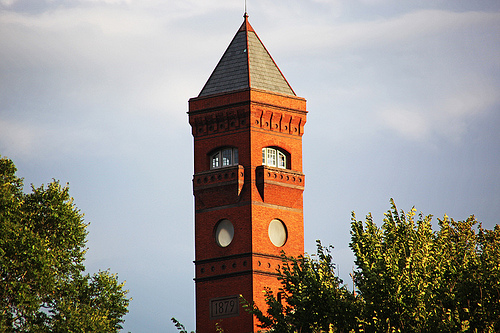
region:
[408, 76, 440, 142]
There is a bright white cloud that is in the distance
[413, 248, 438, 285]
There is a green tree that is visible here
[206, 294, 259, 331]
This tower says "1879" on it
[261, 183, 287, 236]
There is a deep red brick color that is evident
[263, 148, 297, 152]
There is a window in this tower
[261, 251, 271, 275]
There are circles that are emblazoned in the building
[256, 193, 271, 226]
There is a gray line that is visible here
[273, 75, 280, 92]
There is a gray roof that is very visible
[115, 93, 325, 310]
Jackson Mingus took this photo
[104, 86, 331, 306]
This photo has a great deal of detail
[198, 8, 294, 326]
red clock tower in center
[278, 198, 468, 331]
green tree below tower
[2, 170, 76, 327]
green tree below tower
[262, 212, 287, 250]
round glass window on tower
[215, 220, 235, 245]
round glass window on tower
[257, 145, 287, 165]
glass windows on tower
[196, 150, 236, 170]
glass windows on tower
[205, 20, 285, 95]
gray roof of tower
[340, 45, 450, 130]
white clouds in sky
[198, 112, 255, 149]
red brick wall of tower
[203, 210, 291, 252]
two round circles on face of tower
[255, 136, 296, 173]
long arched window on front of tower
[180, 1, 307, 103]
steeple at top of tower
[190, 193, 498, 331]
tall green tree tops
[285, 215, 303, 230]
red bricks on front of tower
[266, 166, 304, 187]
round circular design on front of tower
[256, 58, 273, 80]
grey tiles on top of tower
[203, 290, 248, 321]
year engraved on front of tower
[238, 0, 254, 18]
metal rod at very top of tower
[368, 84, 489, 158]
misty white cloud in grey sky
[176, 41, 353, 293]
a building with a window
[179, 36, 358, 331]
a tall building with a window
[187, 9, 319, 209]
a building with a pointed top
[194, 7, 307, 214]
a building with a pointed ceiling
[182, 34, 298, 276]
a tall building with a pointed top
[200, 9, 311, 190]
a building with pointed ceiling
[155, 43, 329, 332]
a building that is tall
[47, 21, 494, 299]
a sky with clouds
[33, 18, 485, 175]
a sky that is blue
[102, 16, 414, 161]
a blue sky with clouds